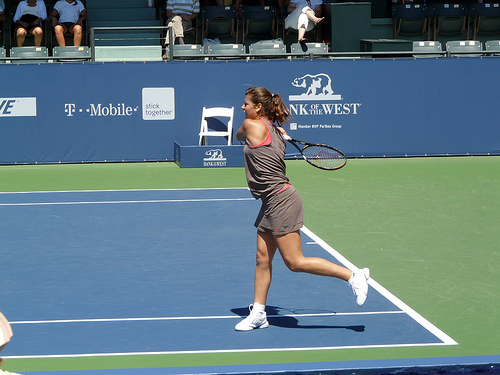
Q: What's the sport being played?
A: Tennis.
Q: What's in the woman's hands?
A: Tennis racquet.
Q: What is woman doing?
A: Swinging.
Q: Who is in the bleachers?
A: Spectators.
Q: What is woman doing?
A: Hitting ball.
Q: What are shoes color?
A: White.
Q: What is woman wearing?
A: Skirt.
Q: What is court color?
A: Green.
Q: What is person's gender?
A: Female.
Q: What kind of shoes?
A: Tennis.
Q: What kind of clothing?
A: Jumpsuit.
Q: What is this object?
A: Racket.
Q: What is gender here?
A: Female.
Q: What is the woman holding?
A: A racket.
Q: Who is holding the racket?
A: A woman.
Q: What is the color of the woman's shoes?
A: White.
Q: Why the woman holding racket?
A: To play.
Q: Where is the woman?
A: In the tennis court.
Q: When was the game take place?
A: Daytime.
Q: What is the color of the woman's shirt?
A: Gray.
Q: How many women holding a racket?
A: One.